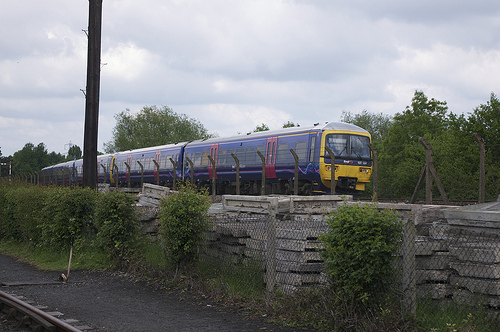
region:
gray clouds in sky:
[1, 2, 498, 154]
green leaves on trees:
[4, 92, 496, 185]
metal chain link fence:
[141, 219, 499, 325]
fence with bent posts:
[93, 138, 497, 196]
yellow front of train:
[320, 121, 375, 188]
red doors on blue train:
[43, 122, 373, 191]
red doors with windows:
[263, 135, 278, 177]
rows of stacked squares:
[149, 196, 499, 293]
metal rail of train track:
[1, 290, 69, 330]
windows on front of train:
[323, 132, 371, 166]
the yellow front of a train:
[317, 126, 375, 193]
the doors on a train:
[260, 137, 277, 174]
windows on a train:
[218, 145, 258, 162]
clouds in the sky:
[165, 38, 315, 105]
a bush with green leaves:
[155, 180, 209, 282]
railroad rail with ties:
[3, 287, 55, 329]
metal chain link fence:
[420, 235, 490, 312]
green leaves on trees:
[396, 98, 486, 138]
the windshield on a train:
[323, 129, 371, 161]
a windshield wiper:
[349, 141, 363, 157]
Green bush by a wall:
[310, 180, 400, 328]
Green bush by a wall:
[151, 174, 214, 284]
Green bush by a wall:
[104, 192, 135, 256]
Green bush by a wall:
[64, 182, 109, 247]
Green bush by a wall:
[34, 177, 88, 247]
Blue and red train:
[182, 117, 389, 197]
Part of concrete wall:
[412, 177, 491, 320]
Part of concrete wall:
[388, 192, 470, 310]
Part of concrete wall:
[265, 184, 332, 314]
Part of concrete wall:
[213, 187, 315, 285]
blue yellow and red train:
[38, 118, 372, 195]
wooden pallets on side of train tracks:
[98, 183, 499, 316]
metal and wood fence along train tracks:
[0, 129, 499, 203]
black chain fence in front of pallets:
[125, 205, 498, 330]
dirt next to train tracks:
[0, 256, 290, 329]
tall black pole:
[78, 0, 111, 191]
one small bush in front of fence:
[314, 198, 400, 318]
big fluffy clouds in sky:
[1, 0, 498, 157]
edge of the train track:
[0, 289, 95, 330]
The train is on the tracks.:
[91, 135, 354, 192]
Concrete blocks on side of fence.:
[214, 195, 441, 290]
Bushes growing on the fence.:
[316, 215, 388, 308]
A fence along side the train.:
[94, 139, 354, 194]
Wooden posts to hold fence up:
[173, 150, 241, 192]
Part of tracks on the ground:
[6, 280, 76, 330]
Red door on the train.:
[251, 130, 278, 170]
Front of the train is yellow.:
[317, 134, 368, 189]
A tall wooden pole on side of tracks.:
[77, 5, 102, 194]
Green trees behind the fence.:
[361, 101, 484, 183]